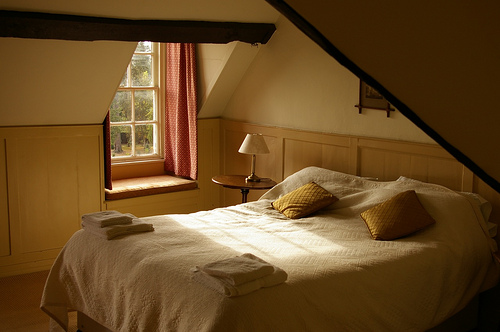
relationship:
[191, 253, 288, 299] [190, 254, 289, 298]
set of folded towels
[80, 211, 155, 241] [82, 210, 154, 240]
set of folded towels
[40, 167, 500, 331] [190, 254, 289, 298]
bed under folded towels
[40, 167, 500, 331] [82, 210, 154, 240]
bed under folded towels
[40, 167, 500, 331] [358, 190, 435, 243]
bed under pillow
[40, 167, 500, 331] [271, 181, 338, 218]
bed under pillow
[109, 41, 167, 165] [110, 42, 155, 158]
window has panes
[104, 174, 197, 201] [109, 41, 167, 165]
seat cushion near window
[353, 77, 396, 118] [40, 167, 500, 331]
picture hanging above bed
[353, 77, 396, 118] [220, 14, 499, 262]
picture on wall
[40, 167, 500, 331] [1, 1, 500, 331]
bed in bedroom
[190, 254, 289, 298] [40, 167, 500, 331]
folded towels are on bed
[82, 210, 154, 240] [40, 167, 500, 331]
folded towels are on bed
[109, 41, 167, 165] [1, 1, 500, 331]
window in bedroom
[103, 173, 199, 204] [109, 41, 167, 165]
bench near window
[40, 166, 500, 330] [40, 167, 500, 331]
bedspread on bed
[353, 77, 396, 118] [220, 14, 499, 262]
picture hanging on wall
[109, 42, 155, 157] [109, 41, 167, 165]
greenery outside of window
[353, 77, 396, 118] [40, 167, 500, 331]
picture over bed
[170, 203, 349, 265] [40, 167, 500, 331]
sunlight shining on bed